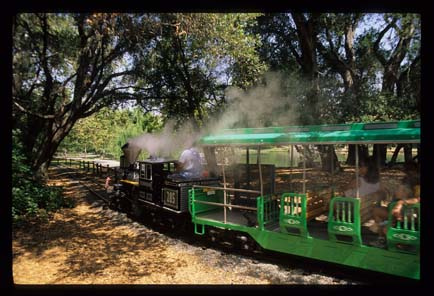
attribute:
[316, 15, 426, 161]
tree — pictured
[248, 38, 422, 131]
tree — pictured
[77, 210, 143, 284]
dirt — brown 